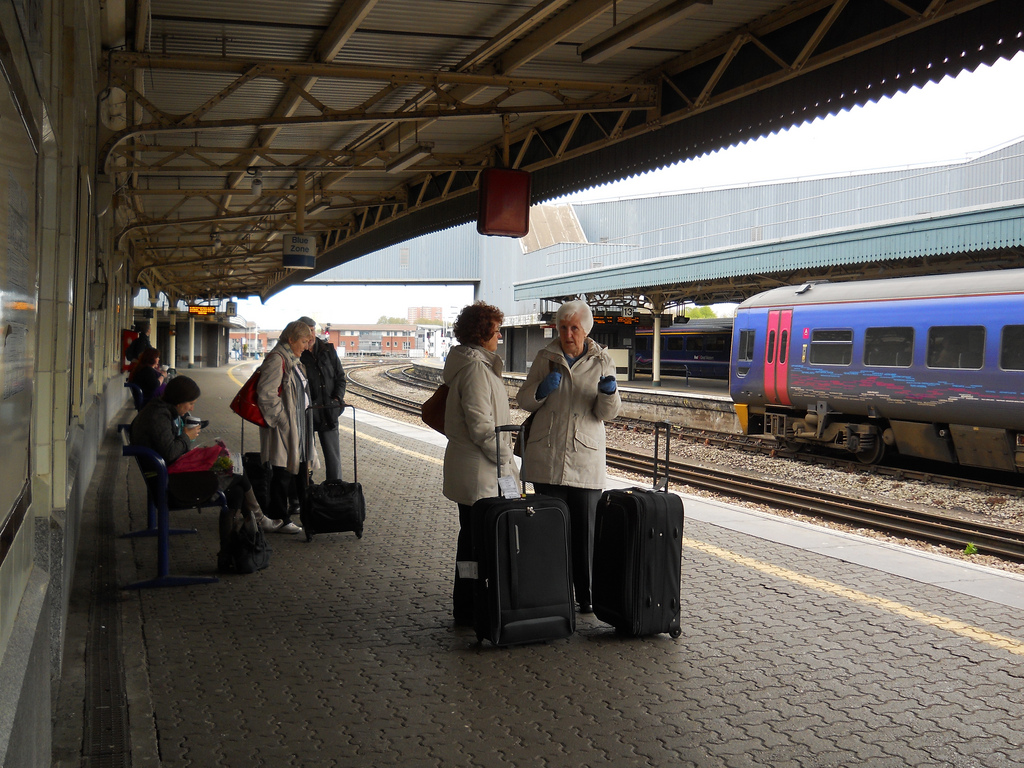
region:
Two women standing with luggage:
[424, 298, 694, 646]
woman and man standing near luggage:
[238, 313, 368, 544]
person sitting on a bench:
[122, 370, 285, 567]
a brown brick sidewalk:
[121, 358, 1019, 761]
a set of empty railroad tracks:
[332, 328, 1022, 569]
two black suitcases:
[450, 418, 691, 641]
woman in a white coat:
[431, 278, 526, 643]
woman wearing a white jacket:
[522, 301, 622, 616]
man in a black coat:
[304, 316, 350, 476]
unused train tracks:
[335, 354, 1022, 554]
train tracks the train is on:
[372, 352, 1021, 486]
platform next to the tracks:
[129, 358, 1022, 766]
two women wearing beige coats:
[429, 288, 623, 637]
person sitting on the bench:
[138, 367, 291, 548]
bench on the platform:
[108, 428, 248, 574]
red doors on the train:
[762, 311, 794, 403]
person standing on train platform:
[250, 322, 313, 538]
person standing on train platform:
[295, 316, 351, 484]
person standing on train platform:
[446, 302, 533, 630]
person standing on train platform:
[513, 298, 625, 619]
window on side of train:
[736, 329, 758, 362]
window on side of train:
[860, 329, 914, 367]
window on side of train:
[925, 327, 985, 372]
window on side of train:
[1004, 323, 1022, 370]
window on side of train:
[810, 329, 855, 367]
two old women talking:
[419, 290, 625, 622]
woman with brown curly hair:
[419, 292, 525, 647]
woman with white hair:
[510, 302, 624, 609]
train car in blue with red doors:
[706, 274, 1023, 477]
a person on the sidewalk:
[547, 230, 655, 633]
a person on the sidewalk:
[433, 244, 567, 636]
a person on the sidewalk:
[275, 285, 353, 530]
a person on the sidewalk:
[90, 303, 274, 592]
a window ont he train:
[813, 320, 842, 375]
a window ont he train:
[936, 314, 1003, 372]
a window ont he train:
[725, 312, 757, 390]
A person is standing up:
[426, 299, 545, 641]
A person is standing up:
[530, 299, 613, 603]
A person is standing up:
[288, 302, 356, 514]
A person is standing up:
[242, 301, 320, 537]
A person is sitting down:
[129, 374, 251, 520]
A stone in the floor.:
[628, 699, 664, 731]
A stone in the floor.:
[596, 727, 634, 759]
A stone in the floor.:
[531, 706, 566, 738]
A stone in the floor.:
[558, 700, 597, 726]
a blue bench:
[119, 390, 219, 583]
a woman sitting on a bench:
[124, 374, 273, 571]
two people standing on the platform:
[256, 310, 380, 535]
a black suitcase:
[468, 487, 568, 631]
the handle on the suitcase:
[487, 421, 526, 494]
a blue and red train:
[732, 294, 1017, 472]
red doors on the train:
[769, 310, 782, 390]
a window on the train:
[808, 326, 853, 361]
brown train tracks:
[342, 355, 1014, 571]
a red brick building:
[226, 321, 432, 351]